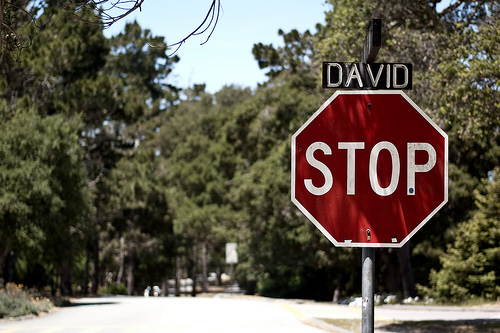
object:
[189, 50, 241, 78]
blue sky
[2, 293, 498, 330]
street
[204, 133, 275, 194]
wall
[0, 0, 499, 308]
grove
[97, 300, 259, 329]
road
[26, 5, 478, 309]
background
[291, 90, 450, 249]
octagon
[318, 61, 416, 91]
sign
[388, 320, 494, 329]
dirt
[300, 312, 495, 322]
median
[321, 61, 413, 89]
david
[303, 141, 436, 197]
white letters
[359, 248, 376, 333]
pole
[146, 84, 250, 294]
trees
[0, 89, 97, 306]
trees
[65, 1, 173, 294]
trees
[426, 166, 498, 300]
trees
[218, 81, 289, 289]
trees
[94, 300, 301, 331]
intersection